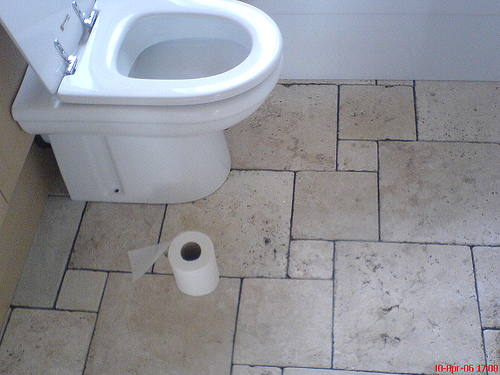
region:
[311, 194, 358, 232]
part of a floor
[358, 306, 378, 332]
part of a floor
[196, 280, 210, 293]
part of a tissue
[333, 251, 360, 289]
part of a floor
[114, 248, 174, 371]
part of a tissue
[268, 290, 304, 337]
part of a floor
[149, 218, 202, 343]
part of a tissue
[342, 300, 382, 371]
part of a floor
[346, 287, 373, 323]
part of a floor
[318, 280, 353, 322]
part of a line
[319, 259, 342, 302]
par tof a floor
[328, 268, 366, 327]
part of a floor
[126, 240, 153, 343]
part of a tissue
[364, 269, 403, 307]
part of a floor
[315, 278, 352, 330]
part of a floor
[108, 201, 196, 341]
part of a tissue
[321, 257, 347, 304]
part of a floor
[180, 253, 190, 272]
part of a tissue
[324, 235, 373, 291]
part of a floor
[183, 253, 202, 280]
part of a tissue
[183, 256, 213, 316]
part of a tissue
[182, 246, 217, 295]
part of a tissue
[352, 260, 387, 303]
part of a floor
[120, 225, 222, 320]
a roll of toilet paper.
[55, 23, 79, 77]
a toilet seat hinge.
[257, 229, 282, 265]
waster on a bathroom floor.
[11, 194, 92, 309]
floor tile next to floor tile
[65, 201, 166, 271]
floor tile next to floor tile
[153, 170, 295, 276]
floor tile next to floor tile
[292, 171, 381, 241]
floor tile next to floor tile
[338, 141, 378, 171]
floor tile next to floor tile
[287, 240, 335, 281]
floor tile next to floor tile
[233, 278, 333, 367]
floor tile next to floor tile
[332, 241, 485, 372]
floor tile next to floor tile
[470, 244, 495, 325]
floor tile next to floor tile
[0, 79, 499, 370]
the dirty tile on floor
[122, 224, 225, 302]
the tissue roll